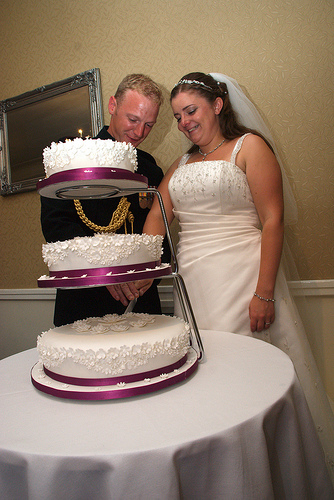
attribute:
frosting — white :
[41, 135, 139, 176]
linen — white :
[0, 325, 331, 498]